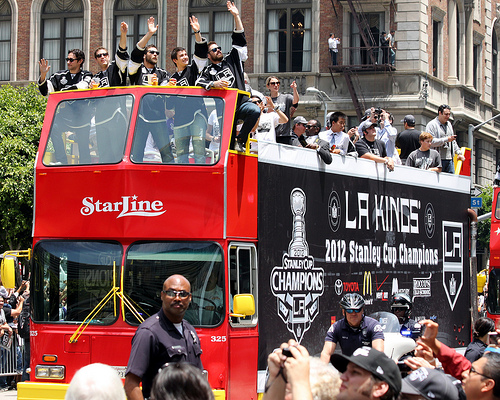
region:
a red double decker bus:
[13, 74, 476, 399]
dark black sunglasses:
[161, 285, 193, 297]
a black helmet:
[339, 290, 366, 310]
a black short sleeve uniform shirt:
[126, 311, 203, 391]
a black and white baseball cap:
[327, 345, 405, 390]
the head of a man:
[461, 352, 498, 397]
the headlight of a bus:
[30, 367, 67, 378]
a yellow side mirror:
[233, 291, 253, 318]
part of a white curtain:
[267, 35, 282, 68]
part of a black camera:
[265, 343, 304, 382]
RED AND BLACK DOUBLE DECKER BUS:
[59, 61, 495, 346]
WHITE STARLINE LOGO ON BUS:
[70, 181, 190, 236]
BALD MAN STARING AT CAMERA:
[126, 264, 226, 384]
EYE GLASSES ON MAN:
[152, 283, 194, 306]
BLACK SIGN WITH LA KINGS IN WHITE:
[312, 182, 444, 239]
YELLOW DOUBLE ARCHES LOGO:
[360, 266, 376, 301]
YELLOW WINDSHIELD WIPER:
[57, 253, 142, 348]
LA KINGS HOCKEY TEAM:
[30, 52, 446, 159]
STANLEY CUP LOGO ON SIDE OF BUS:
[263, 168, 320, 343]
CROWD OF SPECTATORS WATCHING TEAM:
[223, 292, 495, 399]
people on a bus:
[18, 26, 268, 184]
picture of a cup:
[263, 198, 332, 325]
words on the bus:
[316, 191, 433, 285]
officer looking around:
[125, 266, 221, 368]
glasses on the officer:
[151, 267, 215, 313]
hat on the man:
[346, 329, 427, 396]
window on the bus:
[25, 232, 157, 332]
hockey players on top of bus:
[46, 23, 362, 128]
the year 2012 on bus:
[307, 231, 357, 282]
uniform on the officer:
[130, 316, 210, 363]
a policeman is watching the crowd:
[125, 270, 220, 399]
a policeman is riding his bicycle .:
[305, 272, 385, 367]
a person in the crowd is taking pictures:
[267, 333, 397, 398]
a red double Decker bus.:
[12, 76, 492, 376]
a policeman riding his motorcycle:
[378, 290, 426, 335]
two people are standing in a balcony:
[315, 0, 400, 66]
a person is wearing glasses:
[457, 360, 497, 375]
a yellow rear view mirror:
[227, 290, 253, 321]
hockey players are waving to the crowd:
[35, 12, 268, 128]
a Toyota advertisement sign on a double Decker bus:
[329, 275, 364, 297]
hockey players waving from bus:
[36, 0, 270, 162]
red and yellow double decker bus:
[15, 85, 472, 399]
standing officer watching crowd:
[122, 274, 214, 399]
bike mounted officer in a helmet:
[321, 290, 387, 362]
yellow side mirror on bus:
[1, 245, 33, 291]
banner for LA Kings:
[257, 140, 474, 389]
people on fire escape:
[326, 28, 396, 62]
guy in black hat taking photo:
[263, 338, 401, 398]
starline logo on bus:
[75, 188, 168, 218]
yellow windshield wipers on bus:
[59, 262, 145, 344]